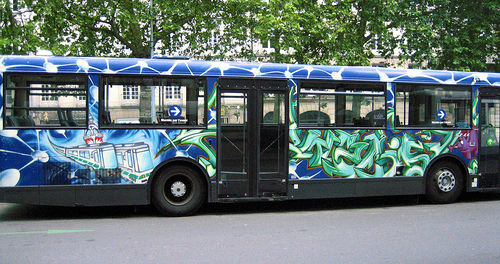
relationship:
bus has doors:
[1, 55, 500, 198] [221, 81, 288, 195]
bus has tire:
[1, 55, 500, 198] [152, 160, 204, 210]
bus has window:
[1, 55, 500, 198] [297, 88, 384, 128]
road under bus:
[5, 196, 500, 263] [1, 55, 500, 198]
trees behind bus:
[5, 3, 498, 73] [1, 55, 500, 198]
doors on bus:
[221, 81, 288, 195] [1, 55, 500, 198]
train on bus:
[65, 145, 152, 179] [1, 55, 500, 198]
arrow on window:
[439, 110, 445, 123] [297, 88, 384, 128]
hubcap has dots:
[436, 170, 454, 191] [442, 171, 451, 177]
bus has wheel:
[1, 55, 500, 198] [426, 162, 466, 202]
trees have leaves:
[5, 3, 498, 73] [9, 4, 390, 52]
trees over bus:
[5, 3, 498, 73] [1, 55, 500, 198]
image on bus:
[454, 128, 480, 158] [1, 55, 500, 198]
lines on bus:
[39, 163, 120, 182] [1, 55, 500, 198]